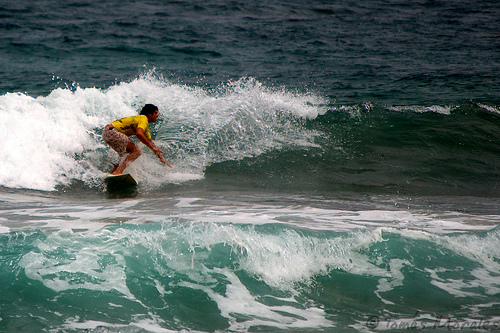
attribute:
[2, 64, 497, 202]
wave — large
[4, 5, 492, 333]
water — white, wavy, greenish, green, bright green, bright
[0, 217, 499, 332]
wave — large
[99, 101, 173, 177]
swimmer — surfing, bent, balancing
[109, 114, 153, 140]
top — yellow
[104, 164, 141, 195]
surfboard — being ridden, floating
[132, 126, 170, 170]
arms — stretched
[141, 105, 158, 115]
hair — black, short, dark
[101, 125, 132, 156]
shorts — patterned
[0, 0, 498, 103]
ocean — open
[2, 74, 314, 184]
foam — white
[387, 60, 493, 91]
wave — small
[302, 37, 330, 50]
wave — small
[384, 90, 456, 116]
foam — white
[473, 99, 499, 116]
foam — white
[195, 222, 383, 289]
foam — white